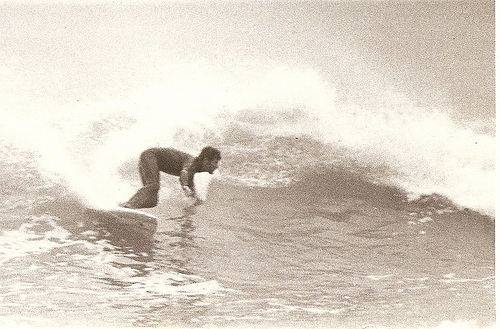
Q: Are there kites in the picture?
A: No, there are no kites.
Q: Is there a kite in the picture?
A: No, there are no kites.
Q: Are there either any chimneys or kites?
A: No, there are no kites or chimneys.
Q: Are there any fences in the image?
A: No, there are no fences.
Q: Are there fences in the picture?
A: No, there are no fences.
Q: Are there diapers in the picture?
A: No, there are no diapers.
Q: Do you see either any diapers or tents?
A: No, there are no diapers or tents.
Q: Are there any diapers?
A: No, there are no diapers.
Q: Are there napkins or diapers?
A: No, there are no diapers or napkins.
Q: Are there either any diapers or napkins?
A: No, there are no diapers or napkins.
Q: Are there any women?
A: No, there are no women.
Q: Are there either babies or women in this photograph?
A: No, there are no women or babies.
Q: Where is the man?
A: The man is in the water.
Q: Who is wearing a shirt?
A: The man is wearing a shirt.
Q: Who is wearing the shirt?
A: The man is wearing a shirt.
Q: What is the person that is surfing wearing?
A: The man is wearing a shirt.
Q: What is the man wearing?
A: The man is wearing a shirt.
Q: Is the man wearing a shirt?
A: Yes, the man is wearing a shirt.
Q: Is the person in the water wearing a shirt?
A: Yes, the man is wearing a shirt.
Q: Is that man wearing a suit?
A: No, the man is wearing a shirt.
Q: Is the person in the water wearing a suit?
A: No, the man is wearing a shirt.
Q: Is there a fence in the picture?
A: No, there are no fences.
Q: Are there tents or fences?
A: No, there are no fences or tents.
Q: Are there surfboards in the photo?
A: Yes, there is a surfboard.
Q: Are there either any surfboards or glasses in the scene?
A: Yes, there is a surfboard.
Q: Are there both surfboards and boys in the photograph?
A: No, there is a surfboard but no boys.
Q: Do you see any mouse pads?
A: No, there are no mouse pads.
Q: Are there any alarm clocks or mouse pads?
A: No, there are no mouse pads or alarm clocks.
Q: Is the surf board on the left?
A: Yes, the surf board is on the left of the image.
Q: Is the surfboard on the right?
A: No, the surfboard is on the left of the image.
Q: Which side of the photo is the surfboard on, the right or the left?
A: The surfboard is on the left of the image.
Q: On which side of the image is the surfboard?
A: The surfboard is on the left of the image.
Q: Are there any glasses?
A: No, there are no glasses.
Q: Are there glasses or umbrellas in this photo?
A: No, there are no glasses or umbrellas.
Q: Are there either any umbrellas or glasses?
A: No, there are no glasses or umbrellas.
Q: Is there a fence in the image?
A: No, there are no fences.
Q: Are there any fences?
A: No, there are no fences.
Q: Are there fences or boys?
A: No, there are no fences or boys.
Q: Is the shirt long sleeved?
A: Yes, the shirt is long sleeved.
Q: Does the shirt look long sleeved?
A: Yes, the shirt is long sleeved.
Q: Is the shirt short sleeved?
A: No, the shirt is long sleeved.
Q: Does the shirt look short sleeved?
A: No, the shirt is long sleeved.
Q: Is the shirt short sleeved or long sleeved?
A: The shirt is long sleeved.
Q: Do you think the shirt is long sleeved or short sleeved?
A: The shirt is long sleeved.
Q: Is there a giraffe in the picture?
A: No, there are no giraffes.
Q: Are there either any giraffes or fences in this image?
A: No, there are no giraffes or fences.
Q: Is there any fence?
A: No, there are no fences.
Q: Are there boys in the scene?
A: No, there are no boys.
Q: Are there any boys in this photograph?
A: No, there are no boys.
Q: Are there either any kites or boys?
A: No, there are no boys or kites.